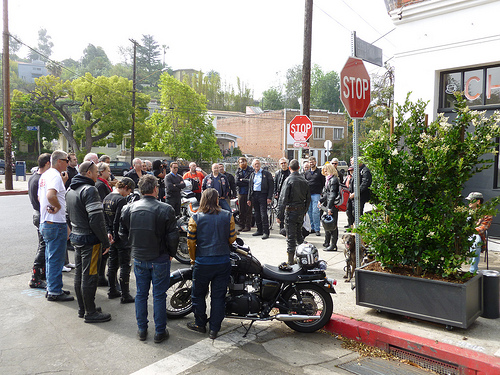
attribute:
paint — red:
[339, 315, 373, 350]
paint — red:
[330, 318, 414, 358]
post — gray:
[296, 2, 327, 157]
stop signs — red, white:
[287, 54, 370, 140]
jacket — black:
[123, 199, 178, 261]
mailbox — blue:
[15, 159, 27, 184]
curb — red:
[373, 330, 428, 354]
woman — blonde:
[316, 158, 346, 255]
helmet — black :
[293, 241, 316, 265]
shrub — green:
[364, 96, 495, 275]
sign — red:
[341, 54, 373, 275]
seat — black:
[244, 250, 300, 276]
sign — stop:
[351, 29, 386, 66]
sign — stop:
[23, 120, 40, 132]